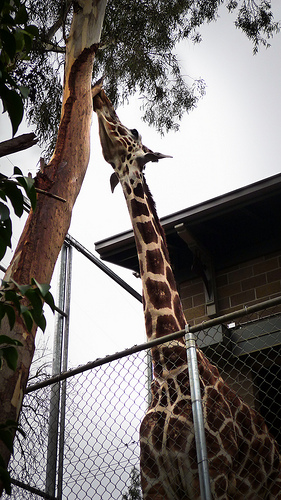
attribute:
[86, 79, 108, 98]
branch — broken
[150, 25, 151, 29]
leaves — hanging 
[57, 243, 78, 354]
poles — metal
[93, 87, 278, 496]
giraffe — reaching, white, eating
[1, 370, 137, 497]
fence — chain link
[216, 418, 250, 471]
spots — brown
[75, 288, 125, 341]
sky — grey, cloudy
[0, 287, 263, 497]
fence — wire, metal, chain link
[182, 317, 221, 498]
post — metal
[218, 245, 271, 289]
wall — brick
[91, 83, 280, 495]
girrafe — brown, spotted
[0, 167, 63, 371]
leaves — green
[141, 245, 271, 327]
building — brick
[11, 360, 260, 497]
fence — chain link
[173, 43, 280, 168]
sky — overcast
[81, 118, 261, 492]
giraffe — striped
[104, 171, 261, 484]
giraffe — striped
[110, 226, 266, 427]
giraffe — striped